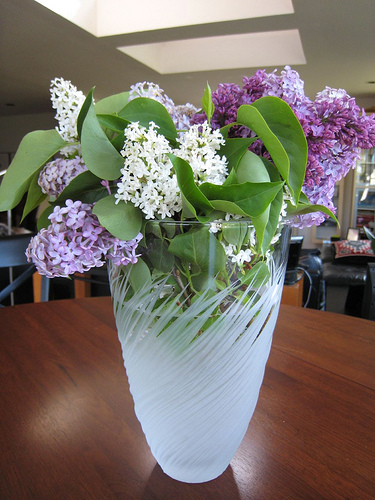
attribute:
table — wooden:
[1, 295, 372, 497]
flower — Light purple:
[22, 189, 136, 280]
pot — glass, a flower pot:
[102, 214, 293, 483]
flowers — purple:
[189, 63, 374, 229]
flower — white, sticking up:
[44, 77, 90, 147]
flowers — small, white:
[22, 57, 368, 292]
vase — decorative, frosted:
[106, 257, 287, 483]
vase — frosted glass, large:
[99, 209, 296, 485]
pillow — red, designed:
[332, 239, 373, 258]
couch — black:
[315, 230, 374, 290]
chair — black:
[1, 229, 99, 298]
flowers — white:
[116, 120, 229, 222]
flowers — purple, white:
[0, 64, 373, 280]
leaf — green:
[0, 129, 65, 211]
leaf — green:
[76, 85, 125, 181]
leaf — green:
[116, 97, 178, 140]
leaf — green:
[91, 195, 143, 240]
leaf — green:
[237, 94, 307, 208]